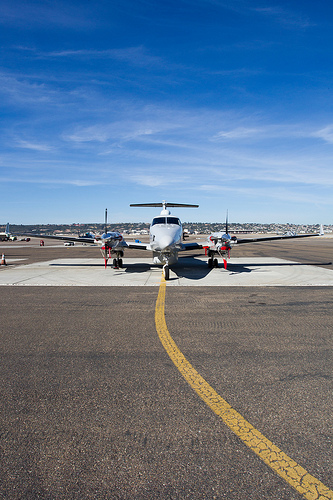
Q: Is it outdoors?
A: Yes, it is outdoors.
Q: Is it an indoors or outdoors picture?
A: It is outdoors.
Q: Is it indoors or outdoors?
A: It is outdoors.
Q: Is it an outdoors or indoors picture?
A: It is outdoors.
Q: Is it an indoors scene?
A: No, it is outdoors.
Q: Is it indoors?
A: No, it is outdoors.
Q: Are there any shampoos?
A: No, there are no shampoos.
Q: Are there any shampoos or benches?
A: No, there are no shampoos or benches.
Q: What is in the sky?
A: The clouds are in the sky.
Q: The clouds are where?
A: The clouds are in the sky.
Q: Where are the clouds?
A: The clouds are in the sky.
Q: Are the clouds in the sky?
A: Yes, the clouds are in the sky.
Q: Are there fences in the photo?
A: No, there are no fences.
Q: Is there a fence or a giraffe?
A: No, there are no fences or giraffes.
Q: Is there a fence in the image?
A: No, there are no fences.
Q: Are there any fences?
A: No, there are no fences.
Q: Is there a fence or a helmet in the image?
A: No, there are no fences or helmets.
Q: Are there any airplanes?
A: Yes, there is an airplane.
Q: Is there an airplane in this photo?
A: Yes, there is an airplane.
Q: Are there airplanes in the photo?
A: Yes, there is an airplane.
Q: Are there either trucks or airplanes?
A: Yes, there is an airplane.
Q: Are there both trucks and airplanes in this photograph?
A: No, there is an airplane but no trucks.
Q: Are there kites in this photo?
A: No, there are no kites.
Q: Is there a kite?
A: No, there are no kites.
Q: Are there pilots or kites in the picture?
A: No, there are no kites or pilots.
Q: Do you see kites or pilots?
A: No, there are no kites or pilots.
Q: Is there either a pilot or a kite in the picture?
A: No, there are no kites or pilots.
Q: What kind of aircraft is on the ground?
A: The aircraft is an airplane.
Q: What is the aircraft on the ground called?
A: The aircraft is an airplane.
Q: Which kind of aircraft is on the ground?
A: The aircraft is an airplane.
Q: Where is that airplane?
A: The airplane is on the ground.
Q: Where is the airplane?
A: The airplane is on the ground.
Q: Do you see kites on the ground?
A: No, there is an airplane on the ground.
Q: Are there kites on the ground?
A: No, there is an airplane on the ground.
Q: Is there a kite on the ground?
A: No, there is an airplane on the ground.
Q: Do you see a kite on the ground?
A: No, there is an airplane on the ground.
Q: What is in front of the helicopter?
A: The plane is in front of the helicopter.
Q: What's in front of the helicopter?
A: The plane is in front of the helicopter.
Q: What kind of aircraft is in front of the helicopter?
A: The aircraft is an airplane.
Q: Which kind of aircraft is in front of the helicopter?
A: The aircraft is an airplane.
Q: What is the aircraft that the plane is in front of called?
A: The aircraft is a helicopter.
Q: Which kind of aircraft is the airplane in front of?
A: The plane is in front of the helicopter.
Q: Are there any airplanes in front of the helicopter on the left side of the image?
A: Yes, there is an airplane in front of the helicopter.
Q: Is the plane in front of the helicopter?
A: Yes, the plane is in front of the helicopter.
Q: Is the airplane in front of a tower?
A: No, the airplane is in front of the helicopter.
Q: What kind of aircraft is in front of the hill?
A: The aircraft is an airplane.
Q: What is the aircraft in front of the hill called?
A: The aircraft is an airplane.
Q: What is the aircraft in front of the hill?
A: The aircraft is an airplane.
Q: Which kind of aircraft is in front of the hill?
A: The aircraft is an airplane.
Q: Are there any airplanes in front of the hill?
A: Yes, there is an airplane in front of the hill.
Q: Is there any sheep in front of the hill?
A: No, there is an airplane in front of the hill.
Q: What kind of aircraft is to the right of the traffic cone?
A: The aircraft is an airplane.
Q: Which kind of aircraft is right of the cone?
A: The aircraft is an airplane.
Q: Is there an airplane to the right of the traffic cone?
A: Yes, there is an airplane to the right of the traffic cone.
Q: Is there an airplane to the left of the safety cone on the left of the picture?
A: No, the airplane is to the right of the traffic cone.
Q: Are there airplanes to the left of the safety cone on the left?
A: No, the airplane is to the right of the traffic cone.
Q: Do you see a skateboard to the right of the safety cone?
A: No, there is an airplane to the right of the safety cone.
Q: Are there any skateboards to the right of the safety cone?
A: No, there is an airplane to the right of the safety cone.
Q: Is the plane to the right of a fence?
A: No, the plane is to the right of the safety cone.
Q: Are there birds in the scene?
A: No, there are no birds.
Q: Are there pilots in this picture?
A: No, there are no pilots.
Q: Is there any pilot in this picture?
A: No, there are no pilots.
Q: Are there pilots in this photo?
A: No, there are no pilots.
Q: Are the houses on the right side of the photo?
A: Yes, the houses are on the right of the image.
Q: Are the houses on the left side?
A: No, the houses are on the right of the image.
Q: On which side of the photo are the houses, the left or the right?
A: The houses are on the right of the image.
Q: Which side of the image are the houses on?
A: The houses are on the right of the image.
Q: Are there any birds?
A: No, there are no birds.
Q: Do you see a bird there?
A: No, there are no birds.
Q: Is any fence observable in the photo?
A: No, there are no fences.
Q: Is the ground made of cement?
A: Yes, the ground is made of cement.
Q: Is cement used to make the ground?
A: Yes, the ground is made of cement.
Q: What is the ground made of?
A: The ground is made of concrete.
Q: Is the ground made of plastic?
A: No, the ground is made of cement.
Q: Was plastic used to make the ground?
A: No, the ground is made of cement.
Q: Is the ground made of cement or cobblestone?
A: The ground is made of cement.